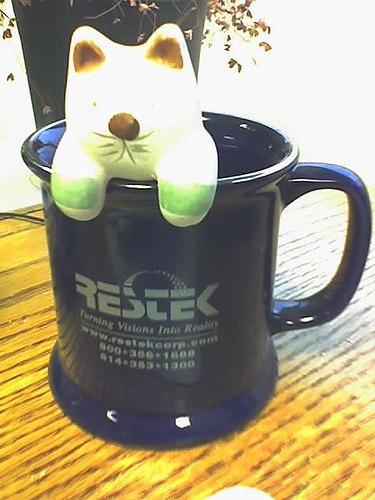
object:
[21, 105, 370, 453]
coffee mug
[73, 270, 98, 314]
large letters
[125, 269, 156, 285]
lines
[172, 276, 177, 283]
dots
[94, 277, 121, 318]
letters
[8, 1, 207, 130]
black vase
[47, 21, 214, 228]
cat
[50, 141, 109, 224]
leg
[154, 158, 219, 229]
leg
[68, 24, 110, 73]
cat ears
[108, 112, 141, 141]
nose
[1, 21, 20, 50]
leaves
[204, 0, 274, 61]
stems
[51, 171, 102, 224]
paws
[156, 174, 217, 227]
paws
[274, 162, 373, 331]
handle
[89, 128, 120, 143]
whiskers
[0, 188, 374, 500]
wooden surface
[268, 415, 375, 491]
lines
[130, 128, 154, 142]
whiskers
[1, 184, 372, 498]
table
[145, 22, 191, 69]
ear